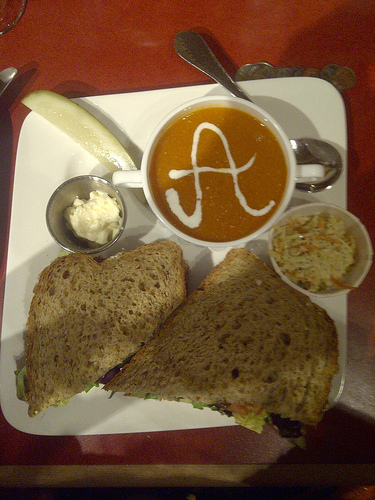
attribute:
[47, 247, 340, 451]
sandwich — two halves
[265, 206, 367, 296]
bowl — small, circular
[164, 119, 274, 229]
sauce — white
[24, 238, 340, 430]
bread — wheat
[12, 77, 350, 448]
plate — white, square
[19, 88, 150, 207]
pickle — a slice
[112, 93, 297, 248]
mug — white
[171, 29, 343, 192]
spoon — metal, silver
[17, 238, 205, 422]
bread — brown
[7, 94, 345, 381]
plate — white, square, porcelain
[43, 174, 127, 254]
metal bowl — circular, small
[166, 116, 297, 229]
tomato soup — orange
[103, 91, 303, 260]
cup — white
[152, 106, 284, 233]
beverage — brown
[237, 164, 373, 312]
container — white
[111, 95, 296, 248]
bowl — white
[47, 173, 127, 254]
container — stainless steel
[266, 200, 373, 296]
cup — white, paper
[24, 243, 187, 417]
bread — brown